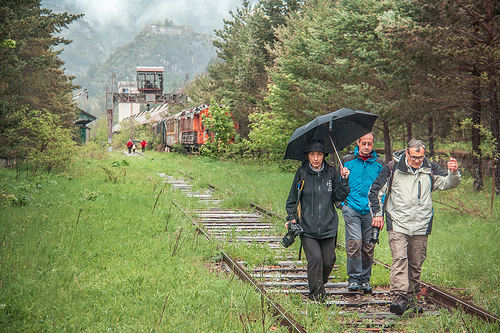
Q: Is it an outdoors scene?
A: Yes, it is outdoors.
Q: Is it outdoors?
A: Yes, it is outdoors.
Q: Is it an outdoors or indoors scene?
A: It is outdoors.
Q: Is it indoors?
A: No, it is outdoors.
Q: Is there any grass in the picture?
A: Yes, there is grass.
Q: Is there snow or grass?
A: Yes, there is grass.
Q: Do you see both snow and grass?
A: No, there is grass but no snow.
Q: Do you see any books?
A: No, there are no books.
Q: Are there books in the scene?
A: No, there are no books.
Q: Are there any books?
A: No, there are no books.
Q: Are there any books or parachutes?
A: No, there are no books or parachutes.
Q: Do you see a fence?
A: No, there are no fences.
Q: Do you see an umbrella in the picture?
A: Yes, there is an umbrella.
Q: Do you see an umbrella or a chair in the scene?
A: Yes, there is an umbrella.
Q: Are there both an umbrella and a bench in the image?
A: No, there is an umbrella but no benches.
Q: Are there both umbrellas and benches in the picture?
A: No, there is an umbrella but no benches.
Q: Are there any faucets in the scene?
A: No, there are no faucets.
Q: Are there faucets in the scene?
A: No, there are no faucets.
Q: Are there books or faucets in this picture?
A: No, there are no faucets or books.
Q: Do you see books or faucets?
A: No, there are no faucets or books.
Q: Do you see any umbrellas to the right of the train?
A: Yes, there is an umbrella to the right of the train.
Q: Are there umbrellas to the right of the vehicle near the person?
A: Yes, there is an umbrella to the right of the train.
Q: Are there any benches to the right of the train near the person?
A: No, there is an umbrella to the right of the train.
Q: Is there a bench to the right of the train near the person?
A: No, there is an umbrella to the right of the train.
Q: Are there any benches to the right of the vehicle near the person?
A: No, there is an umbrella to the right of the train.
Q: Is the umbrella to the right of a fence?
A: No, the umbrella is to the right of the train.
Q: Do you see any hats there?
A: Yes, there is a hat.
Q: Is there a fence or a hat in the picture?
A: Yes, there is a hat.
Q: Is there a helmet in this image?
A: No, there are no helmets.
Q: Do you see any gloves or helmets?
A: No, there are no helmets or gloves.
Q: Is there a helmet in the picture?
A: No, there are no helmets.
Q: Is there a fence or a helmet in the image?
A: No, there are no helmets or fences.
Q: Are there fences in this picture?
A: No, there are no fences.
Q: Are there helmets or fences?
A: No, there are no fences or helmets.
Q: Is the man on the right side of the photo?
A: Yes, the man is on the right of the image.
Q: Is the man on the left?
A: No, the man is on the right of the image.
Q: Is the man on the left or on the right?
A: The man is on the right of the image.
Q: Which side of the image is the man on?
A: The man is on the right of the image.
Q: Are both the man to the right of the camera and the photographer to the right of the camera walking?
A: Yes, both the man and the photographer are walking.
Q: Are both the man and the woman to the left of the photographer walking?
A: Yes, both the man and the woman are walking.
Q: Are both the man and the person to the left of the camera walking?
A: Yes, both the man and the woman are walking.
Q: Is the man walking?
A: Yes, the man is walking.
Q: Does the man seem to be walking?
A: Yes, the man is walking.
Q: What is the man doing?
A: The man is walking.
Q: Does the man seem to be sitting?
A: No, the man is walking.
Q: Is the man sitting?
A: No, the man is walking.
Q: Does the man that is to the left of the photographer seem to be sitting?
A: No, the man is walking.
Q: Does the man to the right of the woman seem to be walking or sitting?
A: The man is walking.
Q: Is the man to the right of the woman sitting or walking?
A: The man is walking.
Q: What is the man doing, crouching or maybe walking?
A: The man is walking.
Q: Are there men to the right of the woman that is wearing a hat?
A: Yes, there is a man to the right of the woman.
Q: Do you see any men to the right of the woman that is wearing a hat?
A: Yes, there is a man to the right of the woman.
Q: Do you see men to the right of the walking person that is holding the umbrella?
A: Yes, there is a man to the right of the woman.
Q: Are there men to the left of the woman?
A: No, the man is to the right of the woman.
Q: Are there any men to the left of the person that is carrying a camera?
A: No, the man is to the right of the woman.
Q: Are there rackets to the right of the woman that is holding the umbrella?
A: No, there is a man to the right of the woman.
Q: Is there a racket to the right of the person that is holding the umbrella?
A: No, there is a man to the right of the woman.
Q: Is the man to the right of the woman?
A: Yes, the man is to the right of the woman.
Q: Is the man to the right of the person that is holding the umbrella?
A: Yes, the man is to the right of the woman.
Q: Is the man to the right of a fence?
A: No, the man is to the right of the woman.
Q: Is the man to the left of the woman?
A: No, the man is to the right of the woman.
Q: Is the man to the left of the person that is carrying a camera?
A: No, the man is to the right of the woman.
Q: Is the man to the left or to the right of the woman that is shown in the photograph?
A: The man is to the right of the woman.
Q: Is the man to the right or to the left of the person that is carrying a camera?
A: The man is to the right of the woman.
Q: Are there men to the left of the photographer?
A: Yes, there is a man to the left of the photographer.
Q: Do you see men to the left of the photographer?
A: Yes, there is a man to the left of the photographer.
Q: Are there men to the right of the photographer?
A: No, the man is to the left of the photographer.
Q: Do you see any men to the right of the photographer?
A: No, the man is to the left of the photographer.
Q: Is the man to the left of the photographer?
A: Yes, the man is to the left of the photographer.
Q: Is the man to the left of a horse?
A: No, the man is to the left of the photographer.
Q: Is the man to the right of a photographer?
A: No, the man is to the left of a photographer.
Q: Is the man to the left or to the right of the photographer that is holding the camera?
A: The man is to the left of the photographer.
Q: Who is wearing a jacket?
A: The man is wearing a jacket.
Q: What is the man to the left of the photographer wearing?
A: The man is wearing a jacket.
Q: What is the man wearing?
A: The man is wearing a jacket.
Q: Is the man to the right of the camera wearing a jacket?
A: Yes, the man is wearing a jacket.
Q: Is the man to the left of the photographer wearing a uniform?
A: No, the man is wearing a jacket.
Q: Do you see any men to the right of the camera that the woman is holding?
A: Yes, there is a man to the right of the camera.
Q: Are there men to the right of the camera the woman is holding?
A: Yes, there is a man to the right of the camera.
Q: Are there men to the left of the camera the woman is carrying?
A: No, the man is to the right of the camera.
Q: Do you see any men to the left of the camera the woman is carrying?
A: No, the man is to the right of the camera.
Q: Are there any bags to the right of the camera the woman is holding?
A: No, there is a man to the right of the camera.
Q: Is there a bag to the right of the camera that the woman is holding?
A: No, there is a man to the right of the camera.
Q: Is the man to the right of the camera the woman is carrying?
A: Yes, the man is to the right of the camera.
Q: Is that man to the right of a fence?
A: No, the man is to the right of the camera.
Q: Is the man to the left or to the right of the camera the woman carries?
A: The man is to the right of the camera.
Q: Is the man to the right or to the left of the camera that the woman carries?
A: The man is to the right of the camera.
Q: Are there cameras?
A: Yes, there is a camera.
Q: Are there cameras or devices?
A: Yes, there is a camera.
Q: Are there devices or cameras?
A: Yes, there is a camera.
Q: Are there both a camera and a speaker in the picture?
A: No, there is a camera but no speakers.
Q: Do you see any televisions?
A: No, there are no televisions.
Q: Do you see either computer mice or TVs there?
A: No, there are no TVs or computer mice.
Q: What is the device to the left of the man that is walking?
A: The device is a camera.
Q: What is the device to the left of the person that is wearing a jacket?
A: The device is a camera.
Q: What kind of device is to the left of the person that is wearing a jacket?
A: The device is a camera.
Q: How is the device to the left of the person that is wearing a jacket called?
A: The device is a camera.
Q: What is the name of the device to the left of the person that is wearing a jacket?
A: The device is a camera.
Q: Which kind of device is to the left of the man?
A: The device is a camera.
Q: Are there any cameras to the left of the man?
A: Yes, there is a camera to the left of the man.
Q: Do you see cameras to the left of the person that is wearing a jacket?
A: Yes, there is a camera to the left of the man.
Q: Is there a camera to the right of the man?
A: No, the camera is to the left of the man.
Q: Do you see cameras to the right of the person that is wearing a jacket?
A: No, the camera is to the left of the man.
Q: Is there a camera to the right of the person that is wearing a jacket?
A: No, the camera is to the left of the man.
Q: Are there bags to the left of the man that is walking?
A: No, there is a camera to the left of the man.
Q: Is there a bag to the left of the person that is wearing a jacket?
A: No, there is a camera to the left of the man.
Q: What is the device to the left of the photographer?
A: The device is a camera.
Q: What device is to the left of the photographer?
A: The device is a camera.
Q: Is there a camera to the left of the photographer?
A: Yes, there is a camera to the left of the photographer.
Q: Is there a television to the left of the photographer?
A: No, there is a camera to the left of the photographer.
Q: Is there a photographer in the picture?
A: Yes, there is a photographer.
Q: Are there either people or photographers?
A: Yes, there is a photographer.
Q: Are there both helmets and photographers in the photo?
A: No, there is a photographer but no helmets.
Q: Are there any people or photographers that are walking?
A: Yes, the photographer is walking.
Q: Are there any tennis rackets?
A: No, there are no tennis rackets.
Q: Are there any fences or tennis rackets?
A: No, there are no tennis rackets or fences.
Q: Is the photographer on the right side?
A: Yes, the photographer is on the right of the image.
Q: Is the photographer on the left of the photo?
A: No, the photographer is on the right of the image.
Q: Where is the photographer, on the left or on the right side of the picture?
A: The photographer is on the right of the image.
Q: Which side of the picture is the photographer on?
A: The photographer is on the right of the image.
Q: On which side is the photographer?
A: The photographer is on the right of the image.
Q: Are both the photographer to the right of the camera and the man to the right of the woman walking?
A: Yes, both the photographer and the man are walking.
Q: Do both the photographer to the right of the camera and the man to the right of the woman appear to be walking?
A: Yes, both the photographer and the man are walking.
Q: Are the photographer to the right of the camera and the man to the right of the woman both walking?
A: Yes, both the photographer and the man are walking.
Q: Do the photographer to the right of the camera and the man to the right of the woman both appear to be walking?
A: Yes, both the photographer and the man are walking.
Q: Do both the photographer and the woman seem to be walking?
A: Yes, both the photographer and the woman are walking.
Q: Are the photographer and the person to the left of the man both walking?
A: Yes, both the photographer and the woman are walking.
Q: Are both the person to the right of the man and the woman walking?
A: Yes, both the photographer and the woman are walking.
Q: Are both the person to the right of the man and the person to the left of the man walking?
A: Yes, both the photographer and the woman are walking.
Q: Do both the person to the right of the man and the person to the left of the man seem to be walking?
A: Yes, both the photographer and the woman are walking.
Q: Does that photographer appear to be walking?
A: Yes, the photographer is walking.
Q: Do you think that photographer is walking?
A: Yes, the photographer is walking.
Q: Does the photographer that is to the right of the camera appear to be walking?
A: Yes, the photographer is walking.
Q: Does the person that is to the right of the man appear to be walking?
A: Yes, the photographer is walking.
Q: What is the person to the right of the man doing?
A: The photographer is walking.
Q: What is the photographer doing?
A: The photographer is walking.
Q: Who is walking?
A: The photographer is walking.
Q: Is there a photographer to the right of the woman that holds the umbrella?
A: Yes, there is a photographer to the right of the woman.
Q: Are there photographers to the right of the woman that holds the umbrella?
A: Yes, there is a photographer to the right of the woman.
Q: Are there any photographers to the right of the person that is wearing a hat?
A: Yes, there is a photographer to the right of the woman.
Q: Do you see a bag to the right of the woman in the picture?
A: No, there is a photographer to the right of the woman.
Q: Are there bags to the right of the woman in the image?
A: No, there is a photographer to the right of the woman.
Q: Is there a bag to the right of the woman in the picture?
A: No, there is a photographer to the right of the woman.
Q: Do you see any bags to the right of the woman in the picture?
A: No, there is a photographer to the right of the woman.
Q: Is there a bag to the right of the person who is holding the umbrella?
A: No, there is a photographer to the right of the woman.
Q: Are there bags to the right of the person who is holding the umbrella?
A: No, there is a photographer to the right of the woman.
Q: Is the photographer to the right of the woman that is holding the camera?
A: Yes, the photographer is to the right of the woman.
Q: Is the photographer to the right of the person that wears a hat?
A: Yes, the photographer is to the right of the woman.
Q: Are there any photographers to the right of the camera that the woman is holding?
A: Yes, there is a photographer to the right of the camera.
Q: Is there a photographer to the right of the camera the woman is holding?
A: Yes, there is a photographer to the right of the camera.